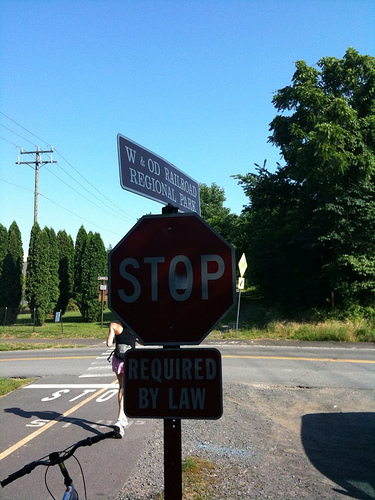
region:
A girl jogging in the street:
[92, 310, 135, 459]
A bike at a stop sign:
[8, 299, 227, 493]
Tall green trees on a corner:
[0, 261, 94, 347]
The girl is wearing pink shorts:
[102, 345, 128, 379]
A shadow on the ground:
[286, 393, 363, 475]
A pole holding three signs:
[93, 125, 245, 491]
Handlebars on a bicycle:
[5, 428, 118, 485]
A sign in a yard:
[43, 306, 68, 329]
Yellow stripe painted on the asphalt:
[21, 385, 74, 447]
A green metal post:
[29, 304, 39, 334]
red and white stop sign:
[98, 207, 245, 345]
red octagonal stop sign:
[99, 210, 243, 350]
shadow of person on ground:
[0, 403, 121, 442]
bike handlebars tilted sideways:
[0, 423, 124, 494]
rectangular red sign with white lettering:
[119, 345, 227, 428]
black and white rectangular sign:
[112, 128, 204, 221]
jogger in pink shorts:
[103, 318, 143, 441]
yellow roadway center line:
[0, 376, 117, 479]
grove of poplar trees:
[1, 211, 111, 337]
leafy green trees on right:
[186, 100, 372, 342]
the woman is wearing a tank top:
[110, 321, 136, 345]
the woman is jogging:
[102, 320, 136, 436]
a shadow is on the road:
[5, 397, 125, 441]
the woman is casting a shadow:
[6, 308, 142, 437]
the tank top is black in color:
[114, 323, 135, 347]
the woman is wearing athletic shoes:
[113, 412, 134, 433]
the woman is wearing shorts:
[109, 358, 130, 375]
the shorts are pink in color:
[111, 356, 127, 374]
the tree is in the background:
[26, 220, 53, 322]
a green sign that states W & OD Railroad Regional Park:
[115, 133, 205, 214]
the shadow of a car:
[288, 396, 374, 491]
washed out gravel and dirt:
[227, 381, 337, 497]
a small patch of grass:
[182, 449, 222, 489]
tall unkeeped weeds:
[266, 315, 371, 344]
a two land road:
[225, 337, 374, 392]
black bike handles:
[0, 434, 123, 489]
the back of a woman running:
[107, 316, 139, 438]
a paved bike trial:
[2, 374, 142, 497]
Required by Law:
[121, 347, 230, 424]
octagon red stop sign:
[104, 211, 238, 346]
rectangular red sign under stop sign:
[122, 344, 223, 418]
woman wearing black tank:
[111, 323, 134, 358]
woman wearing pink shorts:
[110, 354, 125, 371]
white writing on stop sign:
[117, 253, 223, 306]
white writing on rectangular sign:
[126, 356, 217, 410]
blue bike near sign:
[0, 429, 121, 497]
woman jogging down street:
[105, 316, 136, 438]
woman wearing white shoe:
[110, 420, 125, 440]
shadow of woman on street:
[4, 406, 115, 435]